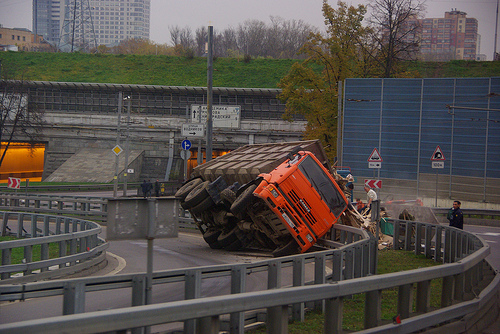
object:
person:
[444, 200, 464, 229]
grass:
[1, 48, 499, 96]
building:
[32, 0, 148, 55]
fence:
[340, 80, 498, 224]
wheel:
[233, 186, 256, 214]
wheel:
[274, 238, 292, 256]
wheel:
[188, 184, 213, 211]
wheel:
[171, 179, 203, 197]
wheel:
[217, 231, 243, 252]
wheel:
[200, 226, 225, 251]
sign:
[8, 174, 19, 191]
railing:
[0, 207, 497, 331]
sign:
[368, 148, 382, 163]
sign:
[431, 146, 448, 163]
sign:
[182, 138, 190, 152]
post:
[434, 171, 440, 222]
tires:
[178, 177, 295, 255]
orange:
[271, 168, 326, 232]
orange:
[303, 145, 351, 204]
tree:
[278, 2, 432, 162]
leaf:
[323, 7, 328, 13]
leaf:
[330, 26, 347, 37]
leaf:
[356, 56, 370, 66]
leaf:
[316, 35, 337, 52]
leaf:
[300, 94, 319, 106]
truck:
[173, 137, 349, 255]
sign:
[191, 101, 242, 133]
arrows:
[184, 106, 200, 138]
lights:
[191, 144, 237, 174]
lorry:
[172, 136, 347, 258]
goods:
[310, 185, 477, 269]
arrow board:
[4, 173, 23, 193]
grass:
[317, 237, 453, 327]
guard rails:
[77, 219, 352, 284]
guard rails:
[398, 219, 497, 324]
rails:
[158, 250, 400, 324]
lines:
[93, 249, 131, 279]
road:
[25, 205, 338, 330]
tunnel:
[9, 133, 81, 188]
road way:
[99, 208, 301, 280]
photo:
[4, 0, 499, 331]